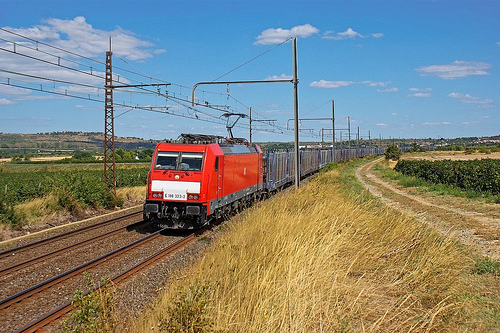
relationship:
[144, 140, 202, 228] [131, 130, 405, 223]
part of the train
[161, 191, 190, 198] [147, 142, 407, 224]
number of the train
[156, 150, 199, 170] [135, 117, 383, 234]
window of the train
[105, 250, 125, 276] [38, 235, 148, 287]
stones inside the track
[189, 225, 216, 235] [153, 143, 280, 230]
wheel of the train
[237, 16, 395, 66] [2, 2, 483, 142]
clouds in sky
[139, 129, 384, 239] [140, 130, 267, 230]
train has engine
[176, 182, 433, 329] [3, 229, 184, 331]
grass next to tracks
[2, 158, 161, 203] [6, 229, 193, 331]
field next to track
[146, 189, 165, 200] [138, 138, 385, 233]
headlight on train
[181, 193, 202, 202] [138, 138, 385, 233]
headlight on train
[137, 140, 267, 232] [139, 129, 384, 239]
car of train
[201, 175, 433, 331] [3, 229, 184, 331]
grass by tracks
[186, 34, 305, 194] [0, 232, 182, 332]
poles over track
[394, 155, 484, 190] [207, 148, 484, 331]
growth in field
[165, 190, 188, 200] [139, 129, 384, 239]
numbers in front of train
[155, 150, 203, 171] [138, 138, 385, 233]
window of train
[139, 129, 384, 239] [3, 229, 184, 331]
train on tracks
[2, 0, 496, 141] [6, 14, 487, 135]
clouds in sky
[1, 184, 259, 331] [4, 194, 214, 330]
gravel beside tracks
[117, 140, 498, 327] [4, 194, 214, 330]
grass beside tracks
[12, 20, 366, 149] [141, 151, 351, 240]
power cables above train